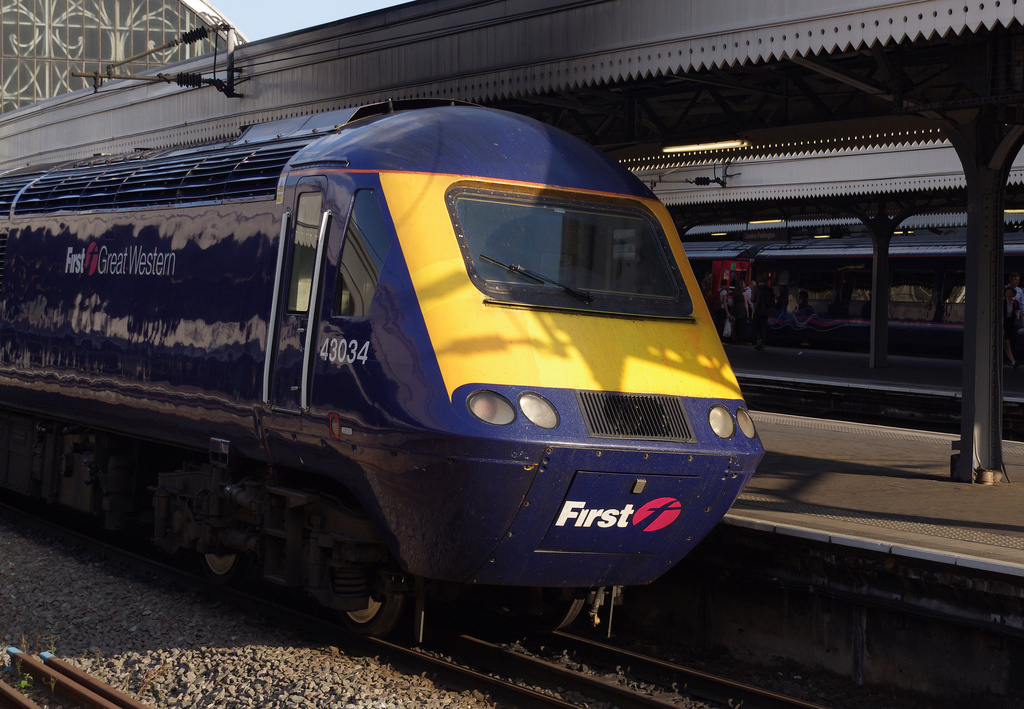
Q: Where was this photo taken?
A: Train station.